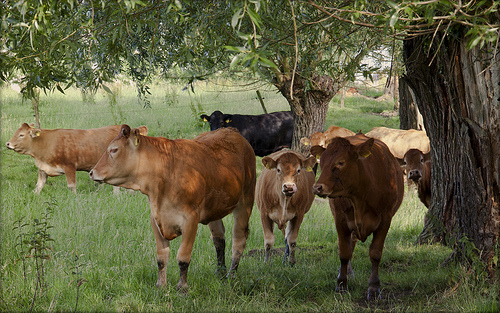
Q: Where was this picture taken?
A: A field.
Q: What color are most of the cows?
A: Brown.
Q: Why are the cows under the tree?
A: To find shade.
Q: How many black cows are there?
A: One.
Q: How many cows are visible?
A: Eight.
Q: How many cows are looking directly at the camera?
A: Two.